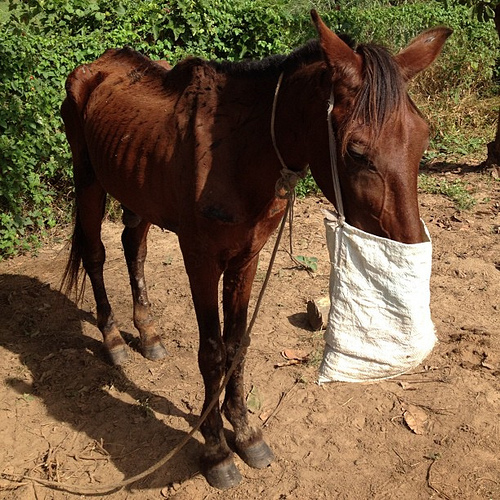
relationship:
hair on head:
[357, 38, 401, 128] [307, 38, 432, 320]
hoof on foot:
[142, 340, 161, 359] [142, 323, 170, 360]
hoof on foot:
[109, 347, 128, 365] [99, 329, 131, 368]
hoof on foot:
[242, 440, 271, 469] [238, 426, 271, 466]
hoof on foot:
[208, 464, 238, 487] [205, 440, 241, 492]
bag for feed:
[325, 216, 440, 391] [315, 231, 428, 377]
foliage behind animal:
[1, 5, 498, 247] [62, 10, 450, 485]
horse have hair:
[62, 10, 450, 485] [357, 38, 401, 128]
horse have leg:
[62, 10, 450, 485] [80, 183, 114, 361]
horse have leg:
[62, 10, 450, 485] [124, 195, 169, 364]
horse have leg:
[62, 10, 450, 485] [183, 240, 233, 480]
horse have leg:
[62, 10, 450, 485] [225, 250, 272, 476]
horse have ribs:
[62, 10, 450, 485] [129, 110, 147, 224]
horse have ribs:
[62, 10, 450, 485] [140, 122, 154, 223]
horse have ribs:
[62, 10, 450, 485] [116, 103, 128, 227]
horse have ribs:
[62, 10, 450, 485] [152, 133, 170, 227]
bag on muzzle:
[325, 216, 440, 391] [325, 183, 430, 319]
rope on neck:
[264, 50, 297, 213] [269, 48, 327, 200]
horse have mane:
[62, 10, 450, 485] [357, 38, 401, 128]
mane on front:
[357, 38, 401, 128] [306, 19, 456, 379]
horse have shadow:
[62, 10, 450, 485] [4, 275, 235, 500]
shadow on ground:
[4, 275, 235, 500] [12, 148, 493, 494]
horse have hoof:
[62, 10, 450, 485] [242, 440, 271, 469]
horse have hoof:
[62, 10, 450, 485] [211, 470, 237, 484]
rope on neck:
[264, 50, 297, 213] [255, 53, 313, 185]